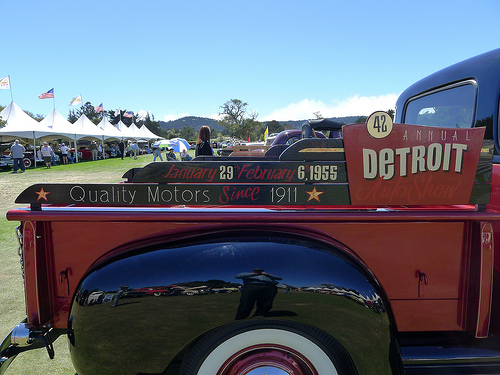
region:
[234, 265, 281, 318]
reflection of photographer in the fender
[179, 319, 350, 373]
an old fashioned white wall tire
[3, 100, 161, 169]
a row of tents with antique cars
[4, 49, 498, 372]
a black and red antique truck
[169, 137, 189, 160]
a blue and white umbrellas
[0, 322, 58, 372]
bumper of the red and black truck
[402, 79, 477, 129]
back window of the pick-up truck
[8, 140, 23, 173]
a man walking by the tents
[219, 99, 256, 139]
a tree at the end of the field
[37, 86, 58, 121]
the flag of the USA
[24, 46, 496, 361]
red truck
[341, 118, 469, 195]
red gold and white sign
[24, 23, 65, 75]
white clouds in blue sky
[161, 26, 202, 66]
white clouds in blue sky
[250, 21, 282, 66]
white clouds in blue sky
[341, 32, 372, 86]
white clouds in blue sky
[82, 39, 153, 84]
white clouds in blue sky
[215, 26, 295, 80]
white clouds in blue sky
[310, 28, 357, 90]
white clouds in blue sky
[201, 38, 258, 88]
white clouds in blue sky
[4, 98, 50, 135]
the tent roof is white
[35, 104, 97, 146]
the tent roof is white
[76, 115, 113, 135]
the tent roof is white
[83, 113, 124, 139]
the tent roof is white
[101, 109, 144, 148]
the tent roof is white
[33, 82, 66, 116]
a waving flag of USA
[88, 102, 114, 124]
a waving flag of USA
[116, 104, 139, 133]
a waving flag of USA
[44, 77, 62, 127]
a waving flag of USA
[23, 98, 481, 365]
the truck is red and black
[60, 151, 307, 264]
Words on the truck.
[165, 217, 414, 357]
Reflection on the truck.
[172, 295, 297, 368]
Wheel on the truck.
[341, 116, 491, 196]
Detroit on the truck.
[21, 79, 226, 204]
Tents on the ground.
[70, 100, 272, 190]
People in the background.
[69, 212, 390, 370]
Shine on the truck.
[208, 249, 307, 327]
Man reflected in the truck.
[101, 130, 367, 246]
Wood railing on the truck.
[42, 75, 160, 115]
Flags on the tents.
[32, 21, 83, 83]
white clouds in blue sky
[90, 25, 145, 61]
white clouds in blue sky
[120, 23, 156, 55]
white clouds in blue sky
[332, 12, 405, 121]
white clouds in blue sky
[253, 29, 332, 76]
white clouds in blue sky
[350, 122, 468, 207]
gold and white sign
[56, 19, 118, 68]
white clouds in blue sky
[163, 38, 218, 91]
white clouds in blue sky